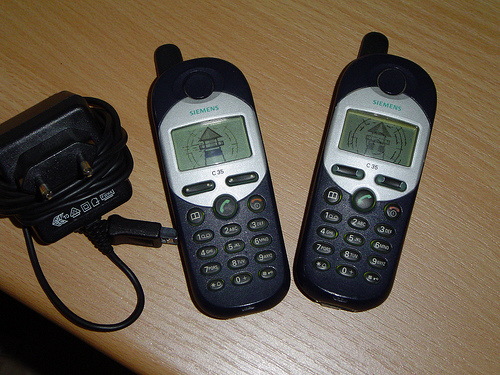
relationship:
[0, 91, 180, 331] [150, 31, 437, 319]
charger for two phones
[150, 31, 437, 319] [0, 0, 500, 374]
two phones on table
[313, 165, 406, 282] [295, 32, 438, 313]
buttons on phone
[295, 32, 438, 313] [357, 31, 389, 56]
phone has an antenna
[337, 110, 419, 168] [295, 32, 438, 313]
screen on phone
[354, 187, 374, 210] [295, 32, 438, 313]
buttons on phone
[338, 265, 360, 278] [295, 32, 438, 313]
0 button on phone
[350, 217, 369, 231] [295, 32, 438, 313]
2 button on phone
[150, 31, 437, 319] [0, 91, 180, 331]
two phones with charger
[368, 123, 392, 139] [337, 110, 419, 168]
triangle on screen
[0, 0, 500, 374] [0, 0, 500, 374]
table made of table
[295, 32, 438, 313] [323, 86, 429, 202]
phone has color gray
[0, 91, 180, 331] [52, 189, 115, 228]
charger has  white symbols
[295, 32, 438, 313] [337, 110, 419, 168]
phone has a screen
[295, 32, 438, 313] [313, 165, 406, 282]
phone has buttons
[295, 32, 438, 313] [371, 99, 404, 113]
phone has company logo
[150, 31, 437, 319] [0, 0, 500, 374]
two phones on a table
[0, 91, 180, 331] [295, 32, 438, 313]
charger for phone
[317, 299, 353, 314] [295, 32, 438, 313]
port on phone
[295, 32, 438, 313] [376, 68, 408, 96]
phone has a speaker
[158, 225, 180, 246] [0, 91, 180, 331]
usb at end of charger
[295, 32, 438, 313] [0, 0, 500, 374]
phone on table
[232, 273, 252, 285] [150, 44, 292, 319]
0 button on phone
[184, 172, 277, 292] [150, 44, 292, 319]
buttons on phone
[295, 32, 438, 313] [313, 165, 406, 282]
phone with a lot of buttons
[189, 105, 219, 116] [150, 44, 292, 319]
siemens on phone